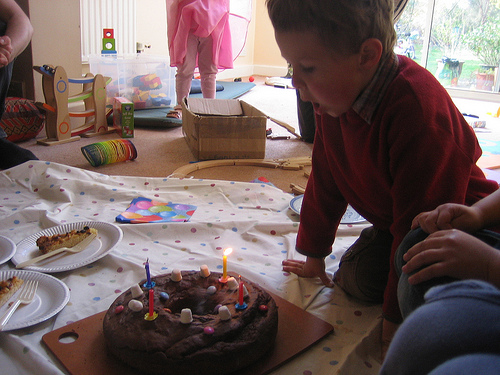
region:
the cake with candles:
[107, 227, 287, 368]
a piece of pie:
[26, 217, 111, 263]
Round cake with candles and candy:
[99, 248, 274, 374]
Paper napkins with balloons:
[116, 188, 199, 228]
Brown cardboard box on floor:
[180, 93, 269, 160]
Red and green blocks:
[100, 26, 118, 55]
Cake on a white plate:
[11, 217, 121, 269]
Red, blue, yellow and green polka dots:
[196, 188, 272, 245]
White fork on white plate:
[0, 273, 72, 339]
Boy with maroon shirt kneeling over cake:
[263, 0, 499, 217]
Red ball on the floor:
[248, 75, 256, 82]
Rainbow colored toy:
[78, 135, 141, 165]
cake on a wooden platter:
[37, 258, 337, 373]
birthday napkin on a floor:
[116, 180, 201, 225]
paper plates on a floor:
[5, 200, 125, 345]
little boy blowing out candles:
[251, 6, 491, 291]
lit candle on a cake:
[212, 240, 237, 285]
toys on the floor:
[40, 57, 150, 167]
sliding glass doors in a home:
[415, 2, 491, 97]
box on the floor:
[166, 86, 276, 161]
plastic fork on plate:
[2, 266, 44, 331]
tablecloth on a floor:
[206, 183, 266, 258]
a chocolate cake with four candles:
[101, 244, 277, 374]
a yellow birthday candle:
[220, 244, 232, 287]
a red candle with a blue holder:
[235, 282, 247, 311]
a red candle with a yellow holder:
[144, 286, 156, 322]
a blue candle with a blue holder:
[143, 256, 155, 290]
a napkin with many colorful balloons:
[114, 195, 197, 222]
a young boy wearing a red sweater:
[264, 1, 499, 356]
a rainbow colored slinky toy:
[79, 137, 139, 167]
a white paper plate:
[9, 219, 122, 272]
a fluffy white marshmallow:
[180, 308, 192, 323]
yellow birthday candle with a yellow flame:
[219, 243, 236, 285]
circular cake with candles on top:
[101, 246, 281, 373]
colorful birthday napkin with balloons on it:
[114, 190, 199, 230]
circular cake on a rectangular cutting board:
[38, 250, 336, 373]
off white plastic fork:
[11, 228, 101, 271]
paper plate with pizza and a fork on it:
[8, 215, 125, 274]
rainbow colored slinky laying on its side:
[71, 135, 150, 170]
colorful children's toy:
[26, 56, 125, 149]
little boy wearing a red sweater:
[259, 0, 499, 330]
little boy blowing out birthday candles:
[1, 0, 498, 374]